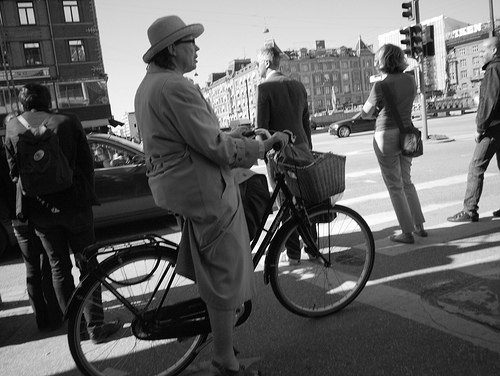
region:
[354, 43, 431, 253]
a woman standing on the street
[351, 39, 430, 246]
a pedestrian waiting to cross the street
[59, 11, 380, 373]
a woman riding a bicycle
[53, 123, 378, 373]
a bicycle with a wicker basket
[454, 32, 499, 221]
a man standing on the street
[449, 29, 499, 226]
a pedestrian waiting to cross the street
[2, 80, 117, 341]
a pedestrian on the sidewalk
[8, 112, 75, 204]
a black backpack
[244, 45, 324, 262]
a man in a suit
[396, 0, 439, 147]
a set of stop signs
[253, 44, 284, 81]
the head of a man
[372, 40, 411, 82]
the head of a woman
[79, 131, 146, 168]
a car window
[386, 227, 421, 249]
the foot of a woman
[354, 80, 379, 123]
the arm of a woman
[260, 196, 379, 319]
a black tire on the bicycle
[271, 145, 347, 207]
a brown wicker basket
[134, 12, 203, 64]
a hat on the woman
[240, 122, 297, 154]
a pair of handlebars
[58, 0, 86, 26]
a window on the building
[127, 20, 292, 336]
the old woman is riding a bike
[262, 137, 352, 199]
the bicycle has a basket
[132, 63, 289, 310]
the woman is wearing a long trench coat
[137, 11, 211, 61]
the woman is wearing a hat with a turned up brim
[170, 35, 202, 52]
the woman is wearing glasses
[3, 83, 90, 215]
the man is wearing a backpack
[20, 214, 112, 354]
the man is wearing dark colored pants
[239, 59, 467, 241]
the people are waiting at the crosswalk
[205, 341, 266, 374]
the woman's foot is on the ground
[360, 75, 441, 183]
the woman is wearing her purse cross body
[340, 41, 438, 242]
woman standing on the sidewalk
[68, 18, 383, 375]
older person on a bike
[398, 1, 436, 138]
tall and thin traffic light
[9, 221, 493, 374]
shadows on the ground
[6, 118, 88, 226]
black backpack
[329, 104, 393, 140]
car driving down the road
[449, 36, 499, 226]
man with his foot popped out, waiting for the signal to change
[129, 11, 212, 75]
hat on top of head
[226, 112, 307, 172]
hands on handle bars of the bike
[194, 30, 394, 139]
building sitting on the kitty corner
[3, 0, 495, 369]
the picture is in black and white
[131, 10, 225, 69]
the woman is wearing a hat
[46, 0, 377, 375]
the woman is on a bicycle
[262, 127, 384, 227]
the bicycle has a basket on front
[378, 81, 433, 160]
the woman is carrying bag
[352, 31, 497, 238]
the people are waiting to cross street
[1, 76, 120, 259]
the man has a backpack on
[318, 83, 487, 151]
cars are passing by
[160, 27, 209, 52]
the woman is wearing glasses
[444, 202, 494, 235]
the man's shoe is black